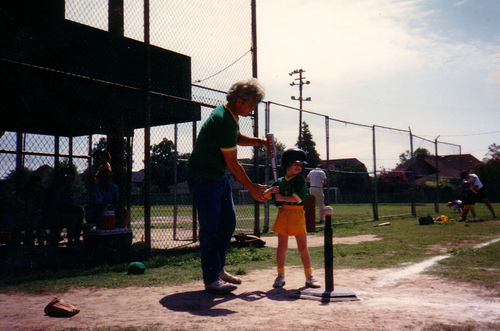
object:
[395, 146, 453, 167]
tree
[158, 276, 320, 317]
shadows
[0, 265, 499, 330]
dirt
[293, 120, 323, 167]
tree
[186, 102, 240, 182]
shirt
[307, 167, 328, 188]
shirt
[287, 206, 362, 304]
tee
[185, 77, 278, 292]
man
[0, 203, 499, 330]
grass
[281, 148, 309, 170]
helmet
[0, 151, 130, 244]
players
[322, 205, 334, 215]
ball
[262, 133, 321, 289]
batter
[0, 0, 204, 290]
dugout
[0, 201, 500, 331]
field